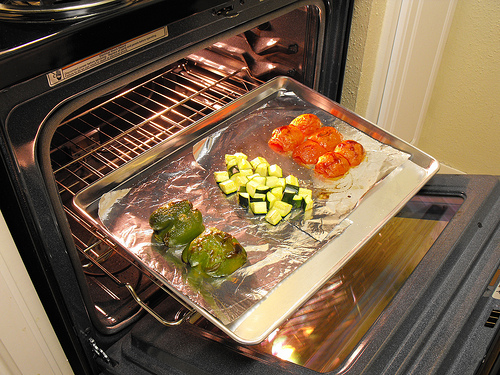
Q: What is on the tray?
A: Veggies.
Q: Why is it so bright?
A: Light is on.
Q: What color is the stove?
A: Black.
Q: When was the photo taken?
A: Dinner time.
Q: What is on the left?
A: Peppers.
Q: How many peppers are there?
A: Two.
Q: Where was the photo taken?
A: In a kitchen.